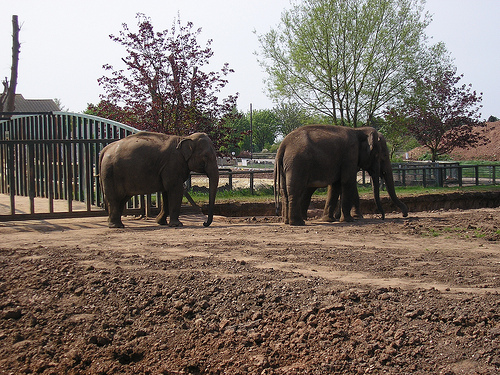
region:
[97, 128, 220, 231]
elephant standing in an enclosure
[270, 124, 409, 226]
an elephant standing in an enclosure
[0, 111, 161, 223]
metal fence around an elephant enclosure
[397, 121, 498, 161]
pile of brown soil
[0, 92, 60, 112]
brown metal roof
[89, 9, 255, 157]
red leaves on a tree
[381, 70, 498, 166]
a tree with red leaves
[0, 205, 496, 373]
dirt floor in an elephant enclosure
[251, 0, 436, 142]
tree with green leaves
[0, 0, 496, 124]
a cloudy grey sky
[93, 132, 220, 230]
A brown elephant.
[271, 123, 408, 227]
Two elephant's standing together.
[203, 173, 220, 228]
The elephant's trunk.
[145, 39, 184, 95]
Part of a tree.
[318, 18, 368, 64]
Part of a tree with green leaves.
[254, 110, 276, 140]
A tree in the background.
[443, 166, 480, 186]
Part of the fence.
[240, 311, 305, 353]
Part of the dirt.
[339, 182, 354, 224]
The elephant's front leg.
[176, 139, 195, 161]
The elephant's ear.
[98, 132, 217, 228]
an elephant standing in an enclosure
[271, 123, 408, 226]
elephants standing side by side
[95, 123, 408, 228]
three elephants standing in an enclosure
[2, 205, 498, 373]
loose dirt covering the ground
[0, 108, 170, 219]
metal fencing near elephant enclosure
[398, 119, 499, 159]
mound of brown soil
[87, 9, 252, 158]
tree with red leaves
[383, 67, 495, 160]
tree with red leaves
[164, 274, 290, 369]
thelland is p[loughet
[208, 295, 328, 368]
the floor is coverd of soil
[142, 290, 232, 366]
the soil is black in color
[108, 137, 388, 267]
two elephants arew alking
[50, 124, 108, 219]
the gate is made of metal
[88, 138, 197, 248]
elephant is bropwn in color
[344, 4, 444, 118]
trees are beside the park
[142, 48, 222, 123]
the trees are purple in color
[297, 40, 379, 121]
the tree is green in color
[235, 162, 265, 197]
the post are wooden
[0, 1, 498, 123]
The sky above the elephants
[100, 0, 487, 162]
Trees near the elephants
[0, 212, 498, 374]
Dirt beneath the elephants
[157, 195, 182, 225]
The front legs of the elephant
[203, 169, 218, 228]
The trunk of the elephant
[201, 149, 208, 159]
The right eye of the elephant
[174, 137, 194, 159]
The right ear of the elephant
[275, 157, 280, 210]
The tail of the elephant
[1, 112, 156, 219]
A fence near the elephants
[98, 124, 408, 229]
Elephants standing in the enclosure